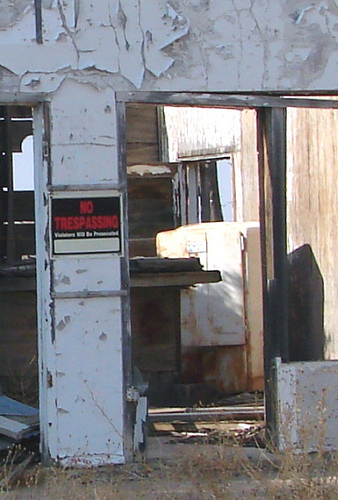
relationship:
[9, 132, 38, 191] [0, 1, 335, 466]
window in back of building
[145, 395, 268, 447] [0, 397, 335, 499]
rubble lying on ground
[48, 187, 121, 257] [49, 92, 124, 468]
sign on wall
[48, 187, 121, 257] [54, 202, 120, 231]
sign says no trespassing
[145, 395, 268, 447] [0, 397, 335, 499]
debris lying on floor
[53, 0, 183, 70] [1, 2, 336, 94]
cracks in wall